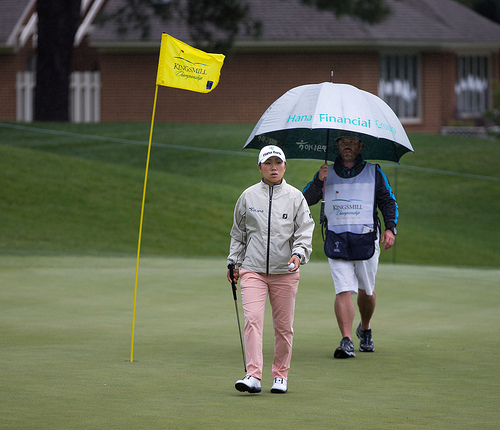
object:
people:
[226, 130, 399, 394]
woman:
[227, 145, 315, 394]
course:
[0, 121, 500, 430]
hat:
[258, 145, 287, 165]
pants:
[239, 267, 300, 380]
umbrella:
[242, 70, 415, 223]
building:
[0, 0, 500, 137]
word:
[287, 113, 396, 136]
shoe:
[235, 374, 262, 393]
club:
[228, 263, 248, 372]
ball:
[288, 262, 295, 268]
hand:
[288, 255, 301, 272]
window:
[379, 54, 423, 120]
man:
[300, 130, 398, 358]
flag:
[128, 31, 224, 360]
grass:
[175, 244, 213, 255]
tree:
[33, 0, 84, 127]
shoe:
[333, 336, 354, 358]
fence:
[13, 72, 101, 123]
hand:
[227, 269, 239, 290]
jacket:
[226, 177, 314, 274]